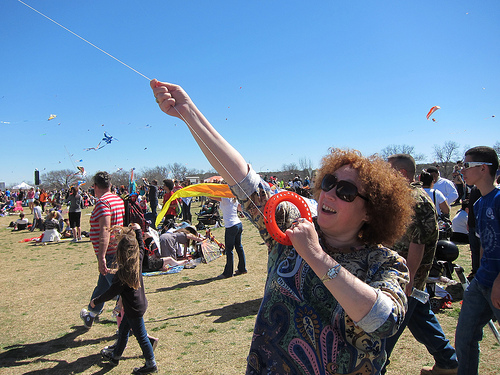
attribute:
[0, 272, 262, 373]
shadows — dark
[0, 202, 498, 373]
ground — grassy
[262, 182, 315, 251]
ring — red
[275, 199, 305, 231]
hole — hollow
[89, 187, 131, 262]
shirt — white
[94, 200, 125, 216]
stripe — red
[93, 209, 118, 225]
stripe — red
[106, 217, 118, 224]
stripe — red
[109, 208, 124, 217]
stripe — red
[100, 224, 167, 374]
child — small, long haired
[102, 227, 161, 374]
girl — little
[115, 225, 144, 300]
hair — long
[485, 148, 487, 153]
hair — curly, red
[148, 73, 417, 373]
woman — red haired, smiling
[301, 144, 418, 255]
hair — curly, reddish brown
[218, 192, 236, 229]
shirt — white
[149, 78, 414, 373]
lady — middle aged, curly haired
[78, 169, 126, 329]
man — older, pointing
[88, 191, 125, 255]
shirt — striped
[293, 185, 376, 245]
smile — toothy, wide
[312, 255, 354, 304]
watch — small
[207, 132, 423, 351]
kite flyer — smiling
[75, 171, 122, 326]
father — old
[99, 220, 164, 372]
daughter — young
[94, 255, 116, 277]
holding hands — tight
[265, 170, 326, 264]
kite reel — professional grade, red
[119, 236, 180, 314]
girl — young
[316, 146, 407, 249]
hair — curly, red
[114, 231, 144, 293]
hair — long, straight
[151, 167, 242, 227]
kite — yellow, orange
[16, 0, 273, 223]
kite string — white, thin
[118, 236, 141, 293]
hair — long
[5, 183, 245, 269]
people — several